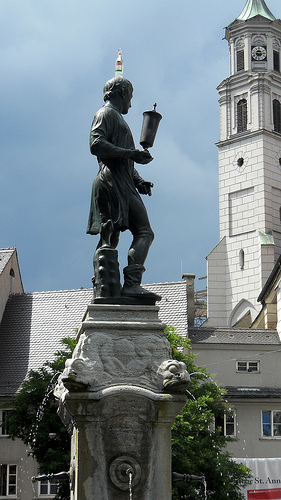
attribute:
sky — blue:
[11, 7, 71, 177]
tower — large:
[201, 1, 277, 324]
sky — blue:
[3, 3, 220, 268]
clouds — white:
[1, 7, 102, 87]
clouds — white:
[169, 5, 215, 143]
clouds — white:
[10, 139, 84, 255]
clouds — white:
[156, 142, 213, 243]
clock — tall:
[251, 45, 265, 59]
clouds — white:
[157, 142, 210, 193]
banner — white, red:
[216, 453, 280, 498]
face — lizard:
[119, 89, 132, 114]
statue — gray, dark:
[86, 74, 163, 305]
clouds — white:
[0, 0, 281, 211]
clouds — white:
[0, 0, 280, 291]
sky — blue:
[0, 0, 279, 291]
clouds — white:
[0, 0, 242, 290]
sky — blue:
[0, 0, 281, 327]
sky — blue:
[2, 3, 88, 247]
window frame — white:
[6, 463, 17, 495]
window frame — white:
[36, 481, 58, 494]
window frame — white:
[260, 409, 280, 436]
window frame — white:
[223, 408, 237, 435]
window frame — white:
[236, 360, 258, 371]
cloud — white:
[132, 52, 235, 210]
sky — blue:
[1, 0, 237, 331]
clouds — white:
[8, 9, 81, 72]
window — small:
[235, 43, 245, 72]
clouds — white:
[0, 4, 190, 78]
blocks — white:
[223, 177, 260, 190]